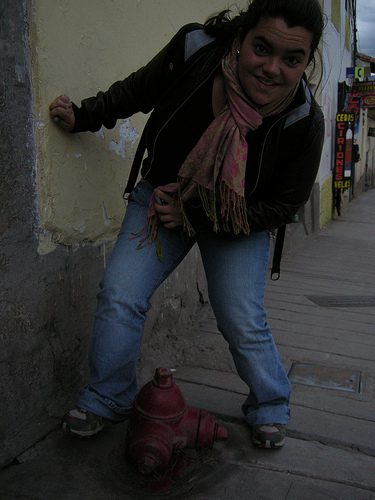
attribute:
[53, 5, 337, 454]
jeans — light-blue, denim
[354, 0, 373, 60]
sky — grey, cloudy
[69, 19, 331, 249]
black shirt — black 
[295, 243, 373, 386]
sidewalk — gray , sidewalk 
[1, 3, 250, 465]
wall — cement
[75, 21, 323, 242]
black jacket — black , woman's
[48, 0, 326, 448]
woman — smiling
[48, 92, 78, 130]
hand — lady's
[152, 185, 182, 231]
hand — lady's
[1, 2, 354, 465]
wall — yellow, cement wall 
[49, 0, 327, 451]
lady — almost falling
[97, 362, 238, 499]
hydrant — fire, red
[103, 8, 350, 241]
jacket — black 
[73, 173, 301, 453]
jeans — blue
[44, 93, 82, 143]
hand — left hand , woman's 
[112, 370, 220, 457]
hydrant — red, fire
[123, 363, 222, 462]
hydrant — fire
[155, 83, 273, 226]
scarf — pink, green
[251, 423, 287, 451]
shoe — grey, tennis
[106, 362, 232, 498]
fire hydrant — red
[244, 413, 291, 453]
shoe — tennis shoes 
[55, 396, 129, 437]
shoe — tennis shoes 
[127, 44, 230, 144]
backpack — woman's